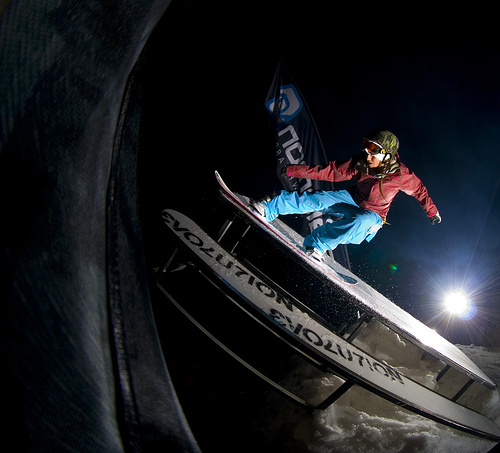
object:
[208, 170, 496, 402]
bench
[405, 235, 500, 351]
light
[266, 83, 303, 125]
logo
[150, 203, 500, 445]
bench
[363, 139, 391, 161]
goggles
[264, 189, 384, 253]
pants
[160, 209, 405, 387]
lettering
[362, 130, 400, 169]
head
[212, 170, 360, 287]
snow board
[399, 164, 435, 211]
arm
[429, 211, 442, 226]
glove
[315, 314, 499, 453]
snow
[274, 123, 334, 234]
letters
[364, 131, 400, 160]
hat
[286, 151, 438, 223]
jacket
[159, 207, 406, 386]
writing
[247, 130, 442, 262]
he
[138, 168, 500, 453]
wall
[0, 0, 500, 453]
outside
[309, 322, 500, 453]
ground